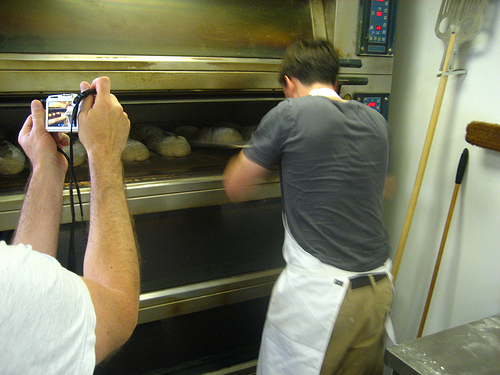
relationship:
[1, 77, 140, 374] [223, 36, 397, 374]
man taking a picture bakers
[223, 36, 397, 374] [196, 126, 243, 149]
bakers baking loaves of bread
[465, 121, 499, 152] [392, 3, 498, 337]
push broom leaning up against white wall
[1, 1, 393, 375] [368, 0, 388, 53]
oven has red and blue digital display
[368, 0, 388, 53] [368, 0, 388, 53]
digital display have a digital display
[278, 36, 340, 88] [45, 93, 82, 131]
bakers head to camera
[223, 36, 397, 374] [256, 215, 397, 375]
bakers wearing a apron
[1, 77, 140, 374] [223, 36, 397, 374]
man is taking a picture bakers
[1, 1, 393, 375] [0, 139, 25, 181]
oven full of baking bread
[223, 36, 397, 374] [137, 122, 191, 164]
bakers has an oven full of baking bread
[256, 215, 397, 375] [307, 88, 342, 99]
apron tied around neck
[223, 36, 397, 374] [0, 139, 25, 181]
bakers busy baking bread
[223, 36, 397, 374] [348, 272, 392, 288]
bakers wearing khaki pants and a brown belt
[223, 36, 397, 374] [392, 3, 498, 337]
bakers long handled spatula is against the wall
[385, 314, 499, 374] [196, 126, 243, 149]
steel cart for transpoting flour rolls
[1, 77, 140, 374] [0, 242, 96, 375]
photographer wearing a white t shirt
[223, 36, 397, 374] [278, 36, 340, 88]
bakers hair brown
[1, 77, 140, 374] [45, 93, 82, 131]
photographers camera white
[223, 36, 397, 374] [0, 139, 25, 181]
bakers oven full of baking bread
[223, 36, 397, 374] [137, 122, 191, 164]
bakers oven full of bread loaves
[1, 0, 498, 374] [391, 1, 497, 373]
bakery has many baking tools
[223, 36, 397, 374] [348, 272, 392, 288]
bakers wearing black belt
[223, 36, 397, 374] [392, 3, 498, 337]
bakers has baking tools against the wall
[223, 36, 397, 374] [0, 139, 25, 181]
bakers a baker baking bread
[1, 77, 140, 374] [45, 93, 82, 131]
man holding camera camera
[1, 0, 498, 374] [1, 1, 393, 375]
bakery has many loaves of bread in the oven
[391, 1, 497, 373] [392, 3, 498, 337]
baking tools and cleaning tools are against the wall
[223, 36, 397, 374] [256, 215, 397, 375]
bakers man in apron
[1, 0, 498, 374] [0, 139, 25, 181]
bakery has a baker baking bread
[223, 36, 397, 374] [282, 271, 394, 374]
bakers wearing khakis and a belt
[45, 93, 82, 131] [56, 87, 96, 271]
digital camera has a black strap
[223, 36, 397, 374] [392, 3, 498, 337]
bakers his baking tools against the wall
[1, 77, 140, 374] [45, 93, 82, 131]
man in white t shirt is taking a picture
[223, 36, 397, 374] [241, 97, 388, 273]
bakers wearing a grey t shirt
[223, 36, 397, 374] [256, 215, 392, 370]
bakers wearing apron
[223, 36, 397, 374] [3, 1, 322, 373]
bakers looking at stove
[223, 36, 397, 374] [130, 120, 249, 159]
bakers baking bread